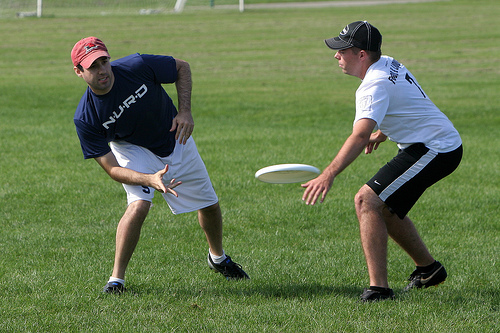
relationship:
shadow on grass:
[154, 255, 405, 331] [121, 256, 452, 331]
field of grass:
[0, 2, 498, 332] [220, 22, 317, 124]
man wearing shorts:
[68, 35, 250, 290] [365, 139, 463, 221]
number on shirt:
[391, 67, 422, 108] [351, 53, 469, 160]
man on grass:
[300, 19, 461, 302] [2, 4, 497, 331]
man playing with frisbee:
[300, 19, 461, 302] [251, 159, 328, 188]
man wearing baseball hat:
[300, 19, 461, 302] [325, 20, 382, 52]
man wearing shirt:
[68, 35, 250, 290] [68, 53, 182, 156]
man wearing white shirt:
[300, 19, 461, 302] [348, 54, 466, 154]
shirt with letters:
[57, 52, 186, 163] [85, 85, 155, 134]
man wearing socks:
[300, 19, 461, 302] [412, 261, 447, 272]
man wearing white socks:
[68, 35, 250, 290] [105, 243, 227, 286]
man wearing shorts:
[300, 19, 461, 302] [326, 110, 453, 214]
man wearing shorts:
[300, 19, 461, 302] [365, 139, 463, 221]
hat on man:
[68, 35, 111, 68] [300, 19, 461, 302]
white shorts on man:
[106, 121, 221, 217] [68, 35, 250, 290]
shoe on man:
[205, 251, 247, 278] [68, 35, 250, 290]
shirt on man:
[357, 55, 464, 153] [300, 19, 461, 302]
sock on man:
[208, 246, 228, 265] [68, 35, 250, 290]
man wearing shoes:
[300, 19, 461, 302] [404, 263, 446, 288]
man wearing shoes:
[300, 19, 461, 302] [361, 260, 451, 307]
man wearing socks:
[257, 15, 458, 326] [51, 255, 248, 274]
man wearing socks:
[300, 19, 461, 302] [365, 253, 437, 281]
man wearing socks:
[68, 35, 250, 299] [95, 243, 227, 298]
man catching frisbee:
[300, 19, 461, 302] [249, 158, 321, 193]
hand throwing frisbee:
[152, 161, 181, 198] [252, 160, 319, 186]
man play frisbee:
[300, 19, 461, 302] [254, 162, 321, 187]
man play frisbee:
[68, 35, 250, 290] [254, 162, 321, 187]